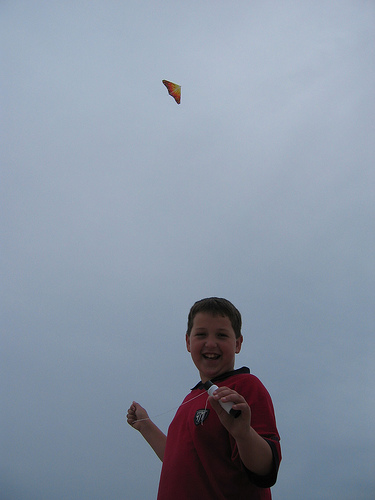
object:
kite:
[161, 78, 182, 105]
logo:
[193, 408, 210, 427]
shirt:
[155, 366, 283, 500]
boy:
[125, 295, 282, 500]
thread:
[129, 388, 209, 426]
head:
[185, 296, 243, 378]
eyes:
[193, 332, 206, 338]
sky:
[1, 141, 375, 274]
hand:
[207, 386, 251, 435]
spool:
[203, 379, 241, 417]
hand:
[124, 401, 147, 430]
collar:
[190, 366, 251, 391]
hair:
[207, 299, 220, 309]